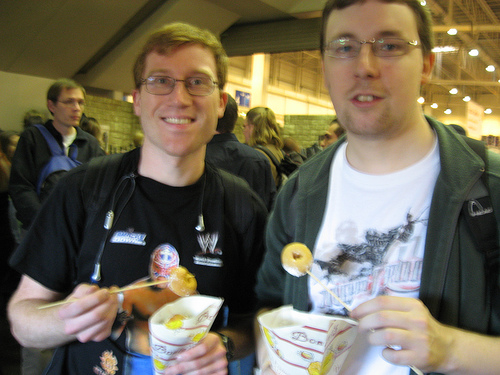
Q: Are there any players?
A: No, there are no players.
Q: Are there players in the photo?
A: No, there are no players.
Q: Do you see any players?
A: No, there are no players.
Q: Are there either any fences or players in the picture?
A: No, there are no players or fences.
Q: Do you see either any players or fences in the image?
A: No, there are no players or fences.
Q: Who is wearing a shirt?
A: The boys are wearing a shirt.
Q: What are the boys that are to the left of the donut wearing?
A: The boys are wearing a shirt.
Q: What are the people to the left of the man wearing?
A: The boys are wearing a shirt.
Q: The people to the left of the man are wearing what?
A: The boys are wearing a shirt.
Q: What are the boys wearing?
A: The boys are wearing a shirt.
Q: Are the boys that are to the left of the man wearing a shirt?
A: Yes, the boys are wearing a shirt.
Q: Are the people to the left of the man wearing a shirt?
A: Yes, the boys are wearing a shirt.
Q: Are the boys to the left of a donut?
A: Yes, the boys are to the left of a donut.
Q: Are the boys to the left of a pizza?
A: No, the boys are to the left of a donut.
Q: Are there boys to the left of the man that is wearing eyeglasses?
A: Yes, there are boys to the left of the man.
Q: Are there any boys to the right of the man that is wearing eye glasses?
A: No, the boys are to the left of the man.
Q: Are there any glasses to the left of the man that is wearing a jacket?
A: No, there are boys to the left of the man.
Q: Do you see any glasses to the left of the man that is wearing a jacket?
A: No, there are boys to the left of the man.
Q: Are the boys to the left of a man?
A: Yes, the boys are to the left of a man.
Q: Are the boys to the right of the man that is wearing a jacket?
A: No, the boys are to the left of the man.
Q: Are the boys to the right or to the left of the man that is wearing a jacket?
A: The boys are to the left of the man.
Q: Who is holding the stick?
A: The boys are holding the stick.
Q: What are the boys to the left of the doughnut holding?
A: The boys are holding the stick.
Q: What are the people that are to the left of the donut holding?
A: The boys are holding the stick.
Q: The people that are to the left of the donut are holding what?
A: The boys are holding the stick.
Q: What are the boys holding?
A: The boys are holding the stick.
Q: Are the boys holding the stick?
A: Yes, the boys are holding the stick.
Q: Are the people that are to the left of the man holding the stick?
A: Yes, the boys are holding the stick.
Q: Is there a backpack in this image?
A: Yes, there is a backpack.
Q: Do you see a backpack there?
A: Yes, there is a backpack.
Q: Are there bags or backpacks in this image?
A: Yes, there is a backpack.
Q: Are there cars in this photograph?
A: No, there are no cars.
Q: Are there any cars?
A: No, there are no cars.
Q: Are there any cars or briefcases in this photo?
A: No, there are no cars or briefcases.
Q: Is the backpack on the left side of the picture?
A: Yes, the backpack is on the left of the image.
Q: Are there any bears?
A: No, there are no bears.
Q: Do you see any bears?
A: No, there are no bears.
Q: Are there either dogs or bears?
A: No, there are no bears or dogs.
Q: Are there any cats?
A: No, there are no cats.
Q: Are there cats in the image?
A: No, there are no cats.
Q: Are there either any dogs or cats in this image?
A: No, there are no cats or dogs.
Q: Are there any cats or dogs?
A: No, there are no cats or dogs.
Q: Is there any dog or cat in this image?
A: No, there are no cats or dogs.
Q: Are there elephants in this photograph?
A: No, there are no elephants.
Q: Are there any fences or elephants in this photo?
A: No, there are no elephants or fences.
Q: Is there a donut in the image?
A: Yes, there is a donut.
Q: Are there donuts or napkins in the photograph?
A: Yes, there is a donut.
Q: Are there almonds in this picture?
A: No, there are no almonds.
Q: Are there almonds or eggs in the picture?
A: No, there are no almonds or eggs.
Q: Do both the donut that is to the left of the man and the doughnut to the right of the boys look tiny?
A: Yes, both the donut and the doughnut are tiny.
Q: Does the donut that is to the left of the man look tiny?
A: Yes, the doughnut is tiny.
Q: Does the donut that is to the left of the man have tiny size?
A: Yes, the doughnut is tiny.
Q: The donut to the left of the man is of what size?
A: The doughnut is tiny.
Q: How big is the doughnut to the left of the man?
A: The donut is tiny.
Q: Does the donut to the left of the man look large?
A: No, the donut is tiny.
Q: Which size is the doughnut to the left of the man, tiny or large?
A: The doughnut is tiny.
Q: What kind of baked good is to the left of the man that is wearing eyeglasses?
A: The food is a donut.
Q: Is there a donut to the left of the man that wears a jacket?
A: Yes, there is a donut to the left of the man.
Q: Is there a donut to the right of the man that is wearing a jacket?
A: No, the donut is to the left of the man.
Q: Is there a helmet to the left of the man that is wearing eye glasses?
A: No, there is a donut to the left of the man.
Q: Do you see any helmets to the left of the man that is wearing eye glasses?
A: No, there is a donut to the left of the man.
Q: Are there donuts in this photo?
A: Yes, there is a donut.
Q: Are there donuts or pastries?
A: Yes, there is a donut.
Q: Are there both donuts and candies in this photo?
A: No, there is a donut but no candies.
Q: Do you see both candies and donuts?
A: No, there is a donut but no candies.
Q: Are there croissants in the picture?
A: No, there are no croissants.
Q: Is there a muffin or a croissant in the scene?
A: No, there are no croissants or muffins.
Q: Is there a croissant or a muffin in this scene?
A: No, there are no croissants or muffins.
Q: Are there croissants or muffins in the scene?
A: No, there are no croissants or muffins.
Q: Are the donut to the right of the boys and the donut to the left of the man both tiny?
A: Yes, both the doughnut and the doughnut are tiny.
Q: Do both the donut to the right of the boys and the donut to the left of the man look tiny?
A: Yes, both the doughnut and the doughnut are tiny.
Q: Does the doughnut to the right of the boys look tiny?
A: Yes, the doughnut is tiny.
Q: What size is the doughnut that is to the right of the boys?
A: The donut is tiny.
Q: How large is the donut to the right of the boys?
A: The donut is tiny.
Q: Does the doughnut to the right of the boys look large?
A: No, the doughnut is tiny.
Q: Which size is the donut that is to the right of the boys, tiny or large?
A: The donut is tiny.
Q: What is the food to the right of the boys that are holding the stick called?
A: The food is a donut.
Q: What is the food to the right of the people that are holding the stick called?
A: The food is a donut.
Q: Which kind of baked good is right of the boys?
A: The food is a donut.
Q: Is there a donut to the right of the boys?
A: Yes, there is a donut to the right of the boys.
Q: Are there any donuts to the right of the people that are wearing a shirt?
A: Yes, there is a donut to the right of the boys.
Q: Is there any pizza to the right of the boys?
A: No, there is a donut to the right of the boys.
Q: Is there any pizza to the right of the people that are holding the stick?
A: No, there is a donut to the right of the boys.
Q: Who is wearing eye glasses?
A: The man is wearing eye glasses.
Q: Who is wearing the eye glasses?
A: The man is wearing eye glasses.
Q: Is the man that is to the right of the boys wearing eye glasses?
A: Yes, the man is wearing eye glasses.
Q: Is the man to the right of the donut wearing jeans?
A: No, the man is wearing eye glasses.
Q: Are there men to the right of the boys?
A: Yes, there is a man to the right of the boys.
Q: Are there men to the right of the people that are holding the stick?
A: Yes, there is a man to the right of the boys.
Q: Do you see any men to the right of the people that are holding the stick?
A: Yes, there is a man to the right of the boys.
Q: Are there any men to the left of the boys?
A: No, the man is to the right of the boys.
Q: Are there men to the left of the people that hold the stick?
A: No, the man is to the right of the boys.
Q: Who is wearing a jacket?
A: The man is wearing a jacket.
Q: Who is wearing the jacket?
A: The man is wearing a jacket.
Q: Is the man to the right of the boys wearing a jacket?
A: Yes, the man is wearing a jacket.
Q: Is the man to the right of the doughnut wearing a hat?
A: No, the man is wearing a jacket.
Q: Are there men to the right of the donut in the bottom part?
A: Yes, there is a man to the right of the doughnut.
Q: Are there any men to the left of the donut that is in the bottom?
A: No, the man is to the right of the donut.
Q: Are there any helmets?
A: No, there are no helmets.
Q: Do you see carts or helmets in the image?
A: No, there are no helmets or carts.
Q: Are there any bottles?
A: No, there are no bottles.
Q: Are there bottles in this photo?
A: No, there are no bottles.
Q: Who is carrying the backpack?
A: The man is carrying the backpack.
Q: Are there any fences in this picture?
A: No, there are no fences.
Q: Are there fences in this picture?
A: No, there are no fences.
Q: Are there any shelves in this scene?
A: No, there are no shelves.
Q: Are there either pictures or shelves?
A: No, there are no shelves or pictures.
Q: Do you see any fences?
A: No, there are no fences.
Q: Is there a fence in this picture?
A: No, there are no fences.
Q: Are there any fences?
A: No, there are no fences.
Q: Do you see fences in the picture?
A: No, there are no fences.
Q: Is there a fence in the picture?
A: No, there are no fences.